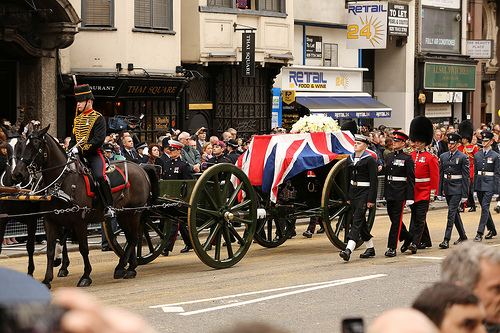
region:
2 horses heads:
[3, 123, 50, 195]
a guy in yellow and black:
[56, 83, 116, 155]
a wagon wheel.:
[180, 162, 264, 273]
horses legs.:
[37, 211, 145, 288]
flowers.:
[287, 107, 344, 133]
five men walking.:
[340, 125, 498, 259]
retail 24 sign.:
[342, 0, 387, 50]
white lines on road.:
[141, 259, 396, 321]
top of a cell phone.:
[322, 310, 366, 331]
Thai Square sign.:
[84, 73, 191, 102]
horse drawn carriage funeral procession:
[5, 76, 391, 264]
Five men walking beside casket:
[345, 115, 497, 252]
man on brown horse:
[25, 55, 155, 280]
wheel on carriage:
[190, 156, 261, 268]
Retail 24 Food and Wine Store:
[276, 55, 456, 130]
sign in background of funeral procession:
[423, 46, 479, 101]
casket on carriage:
[238, 128, 385, 213]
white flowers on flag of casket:
[288, 104, 351, 139]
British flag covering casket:
[231, 137, 379, 198]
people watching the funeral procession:
[131, 123, 255, 167]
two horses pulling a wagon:
[6, 110, 377, 293]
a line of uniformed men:
[341, 125, 498, 265]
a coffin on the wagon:
[158, 127, 389, 252]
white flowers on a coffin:
[241, 112, 378, 198]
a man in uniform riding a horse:
[8, 79, 153, 286]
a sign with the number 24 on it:
[343, 2, 390, 54]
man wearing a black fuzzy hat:
[408, 115, 440, 255]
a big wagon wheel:
[180, 155, 264, 273]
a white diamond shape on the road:
[148, 298, 193, 320]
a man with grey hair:
[437, 232, 499, 324]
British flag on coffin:
[223, 122, 376, 197]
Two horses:
[5, 112, 186, 281]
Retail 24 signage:
[342, 0, 392, 55]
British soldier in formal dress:
[338, 111, 495, 264]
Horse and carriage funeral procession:
[16, 80, 392, 289]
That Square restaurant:
[73, 62, 207, 194]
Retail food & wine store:
[263, 51, 418, 199]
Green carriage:
[157, 168, 397, 271]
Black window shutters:
[73, 0, 182, 55]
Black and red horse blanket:
[68, 149, 136, 202]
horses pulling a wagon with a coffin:
[3, 112, 384, 289]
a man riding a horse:
[11, 83, 161, 293]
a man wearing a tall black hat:
[408, 116, 442, 253]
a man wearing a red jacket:
[407, 116, 441, 251]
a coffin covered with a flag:
[227, 130, 376, 203]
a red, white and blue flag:
[229, 131, 379, 206]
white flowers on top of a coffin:
[232, 111, 377, 200]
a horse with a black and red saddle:
[11, 122, 162, 289]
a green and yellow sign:
[424, 61, 479, 91]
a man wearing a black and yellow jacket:
[63, 83, 123, 240]